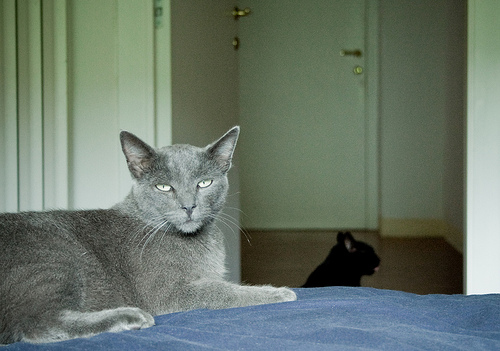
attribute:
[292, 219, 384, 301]
cat — black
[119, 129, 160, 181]
ear — pointy, cat's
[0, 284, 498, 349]
blanket — blue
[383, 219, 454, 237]
wall trim — tan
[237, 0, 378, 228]
door — closed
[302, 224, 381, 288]
cat — black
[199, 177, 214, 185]
eye — glowing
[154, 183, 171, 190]
eye — glowing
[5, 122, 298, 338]
cat — grey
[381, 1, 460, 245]
walls — white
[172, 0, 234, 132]
walls — white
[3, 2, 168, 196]
walls — white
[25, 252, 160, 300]
fur — grey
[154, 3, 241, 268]
door — white, opened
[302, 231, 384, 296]
cat — occupying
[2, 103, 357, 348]
cat — grey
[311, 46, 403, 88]
handle — gold, door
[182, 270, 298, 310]
leg — cat's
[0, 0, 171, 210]
wall — white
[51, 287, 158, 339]
foot — grey, cat's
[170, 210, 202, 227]
mouth — cat's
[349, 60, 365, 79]
knob — bronze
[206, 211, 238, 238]
whiskers — white, cat's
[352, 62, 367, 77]
doorknob — gold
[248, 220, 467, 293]
floor — brown 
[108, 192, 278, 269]
whiskers — flowing, white, cat's